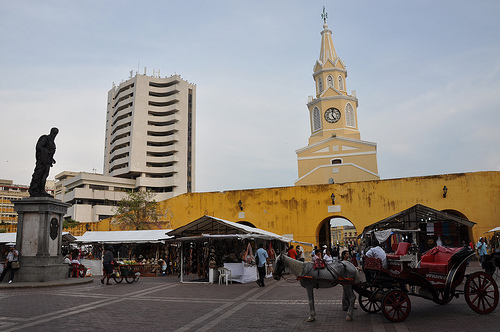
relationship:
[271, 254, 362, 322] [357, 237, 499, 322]
horse pulling a carriage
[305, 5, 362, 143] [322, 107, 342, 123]
tower has a clock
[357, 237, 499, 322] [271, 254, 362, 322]
carriage being pulled by a horse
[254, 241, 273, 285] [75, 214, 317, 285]
person walking around tent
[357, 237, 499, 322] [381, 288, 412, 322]
carriage has a wheel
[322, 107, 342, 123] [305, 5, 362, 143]
clock on tower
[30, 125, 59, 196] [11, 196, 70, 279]
statue on a base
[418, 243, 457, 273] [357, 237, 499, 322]
seat on carriage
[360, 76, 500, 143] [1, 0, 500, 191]
clouds are in sky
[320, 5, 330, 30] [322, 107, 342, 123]
steeple with a clock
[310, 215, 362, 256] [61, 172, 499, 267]
archway on wall